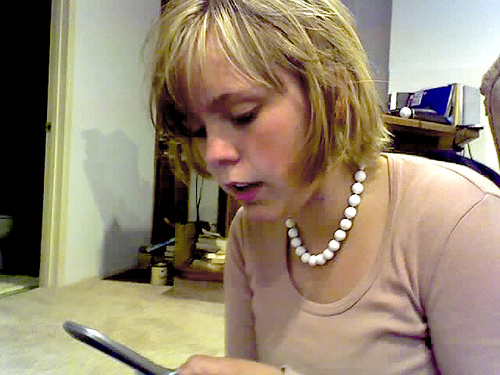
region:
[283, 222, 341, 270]
White pearl looking necklace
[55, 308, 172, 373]
Top part of a mobile phone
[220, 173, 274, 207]
A slightly open mouth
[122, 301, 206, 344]
A yellow floor rug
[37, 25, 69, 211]
A metal door frame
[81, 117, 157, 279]
A shadow on the wall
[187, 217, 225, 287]
A stack of books on the shelf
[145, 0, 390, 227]
A young girl with short blonde hair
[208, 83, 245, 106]
an eyebrow on a face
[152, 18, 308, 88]
Baangs on the forehead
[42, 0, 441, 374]
A young woman using a cell phone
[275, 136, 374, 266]
White pearl necklace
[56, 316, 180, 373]
Flip phone in girl's hand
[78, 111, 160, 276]
Shadow on the wall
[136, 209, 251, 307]
Lots of books stacked up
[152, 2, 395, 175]
Messy short blond hair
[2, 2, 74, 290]
Door way to another room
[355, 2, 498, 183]
Wall covered in white paint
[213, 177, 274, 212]
Dark pink lipstick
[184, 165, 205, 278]
Wires hanging down onto the floor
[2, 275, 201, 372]
Linoleum floor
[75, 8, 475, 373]
a young girl on her phone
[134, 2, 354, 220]
the head of a woman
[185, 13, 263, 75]
the bangs of a woman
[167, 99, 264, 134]
the eyes of a woman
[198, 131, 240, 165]
the nose of a woman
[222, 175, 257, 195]
the mouth of a woman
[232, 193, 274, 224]
the chin of a woman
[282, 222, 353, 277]
the pearls of a woman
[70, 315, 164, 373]
the cell phone of a woman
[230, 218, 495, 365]
the pink shirt of a woman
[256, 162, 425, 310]
string of pearls on a neck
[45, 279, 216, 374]
a silver cell phone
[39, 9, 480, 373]
a lady looking at her phone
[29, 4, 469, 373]
lady looking at cell phone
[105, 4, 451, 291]
lady with short blonde hair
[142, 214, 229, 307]
a pile of books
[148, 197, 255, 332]
assorted books on the floor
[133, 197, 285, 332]
assorted paper back books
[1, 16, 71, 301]
door way into bathroom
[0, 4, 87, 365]
door way into a dark bathroom